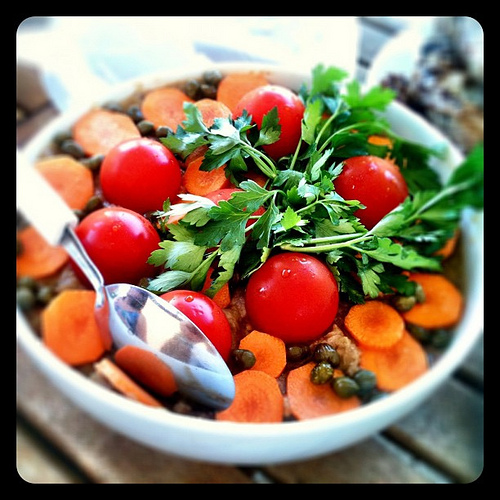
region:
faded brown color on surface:
[376, 435, 451, 465]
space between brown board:
[236, 467, 284, 482]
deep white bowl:
[24, 63, 477, 442]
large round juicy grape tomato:
[240, 255, 337, 337]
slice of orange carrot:
[348, 304, 400, 341]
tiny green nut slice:
[233, 345, 253, 362]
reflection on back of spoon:
[106, 295, 213, 361]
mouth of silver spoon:
[63, 257, 285, 394]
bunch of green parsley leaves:
[218, 175, 423, 273]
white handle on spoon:
[23, 180, 85, 223]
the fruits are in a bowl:
[2, 50, 477, 498]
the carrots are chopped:
[3, 80, 444, 477]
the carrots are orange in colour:
[255, 352, 375, 427]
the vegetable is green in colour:
[144, 100, 478, 327]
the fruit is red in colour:
[183, 245, 385, 375]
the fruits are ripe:
[228, 250, 351, 350]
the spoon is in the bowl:
[11, 139, 288, 417]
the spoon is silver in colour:
[23, 216, 278, 431]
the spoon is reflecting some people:
[69, 245, 250, 410]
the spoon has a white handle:
[19, 131, 103, 255]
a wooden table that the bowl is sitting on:
[18, 350, 488, 483]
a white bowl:
[18, 64, 498, 461]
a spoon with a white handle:
[13, 146, 259, 433]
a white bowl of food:
[19, 80, 479, 403]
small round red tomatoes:
[73, 68, 428, 353]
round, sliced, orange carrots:
[27, 87, 489, 432]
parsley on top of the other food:
[147, 77, 463, 322]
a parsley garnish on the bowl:
[141, 67, 472, 286]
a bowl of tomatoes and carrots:
[21, 90, 486, 455]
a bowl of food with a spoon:
[18, 68, 493, 466]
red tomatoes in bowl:
[114, 94, 335, 342]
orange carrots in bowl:
[81, 105, 361, 415]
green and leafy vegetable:
[207, 80, 437, 290]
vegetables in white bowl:
[75, 87, 382, 419]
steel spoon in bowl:
[5, 168, 253, 400]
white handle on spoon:
[7, 130, 79, 274]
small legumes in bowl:
[302, 315, 414, 409]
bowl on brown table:
[104, 70, 448, 474]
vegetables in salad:
[88, 70, 419, 464]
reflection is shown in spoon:
[61, 235, 248, 426]